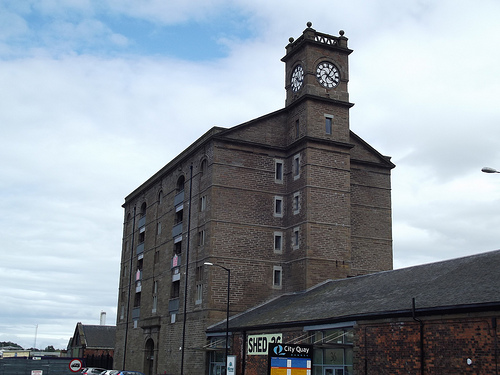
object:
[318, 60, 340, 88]
clock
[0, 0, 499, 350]
clouds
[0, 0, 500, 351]
sky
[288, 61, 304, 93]
clocks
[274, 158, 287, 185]
opening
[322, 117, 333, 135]
window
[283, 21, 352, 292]
tower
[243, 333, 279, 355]
sign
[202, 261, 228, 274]
light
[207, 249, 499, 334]
roof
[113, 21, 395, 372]
building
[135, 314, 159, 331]
overhang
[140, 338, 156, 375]
door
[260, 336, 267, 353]
letters